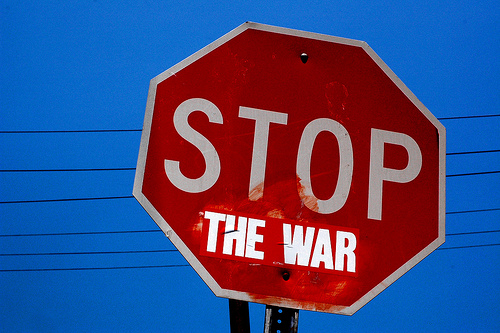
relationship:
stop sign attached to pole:
[130, 17, 446, 314] [257, 305, 301, 332]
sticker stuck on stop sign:
[195, 203, 359, 278] [130, 17, 446, 314]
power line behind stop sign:
[0, 111, 499, 134] [130, 17, 446, 314]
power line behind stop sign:
[1, 149, 499, 176] [130, 17, 446, 314]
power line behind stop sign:
[0, 169, 499, 207] [130, 17, 446, 314]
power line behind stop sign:
[1, 206, 497, 236] [130, 17, 446, 314]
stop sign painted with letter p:
[130, 17, 446, 314] [365, 122, 423, 220]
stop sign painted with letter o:
[130, 17, 446, 314] [293, 117, 354, 214]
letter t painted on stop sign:
[236, 102, 290, 204] [130, 17, 446, 314]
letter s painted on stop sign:
[161, 95, 225, 192] [130, 17, 446, 314]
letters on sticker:
[204, 210, 355, 272] [195, 203, 359, 278]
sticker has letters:
[195, 203, 359, 278] [204, 210, 355, 272]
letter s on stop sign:
[161, 95, 225, 192] [130, 17, 446, 314]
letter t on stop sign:
[236, 102, 290, 204] [130, 17, 446, 314]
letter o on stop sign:
[293, 117, 354, 214] [130, 17, 446, 314]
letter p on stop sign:
[365, 122, 423, 220] [130, 17, 446, 314]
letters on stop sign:
[204, 210, 355, 272] [130, 17, 446, 314]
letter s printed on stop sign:
[161, 95, 225, 192] [130, 17, 446, 314]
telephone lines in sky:
[0, 108, 499, 278] [1, 0, 499, 333]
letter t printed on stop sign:
[236, 102, 290, 204] [130, 17, 446, 314]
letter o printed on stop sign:
[293, 117, 354, 214] [130, 17, 446, 314]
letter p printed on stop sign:
[365, 122, 423, 220] [130, 17, 446, 314]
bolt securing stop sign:
[277, 268, 293, 281] [130, 17, 446, 314]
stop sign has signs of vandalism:
[130, 17, 446, 314] [189, 171, 359, 313]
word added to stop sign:
[202, 210, 267, 260] [130, 17, 446, 314]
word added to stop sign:
[280, 220, 358, 276] [130, 17, 446, 314]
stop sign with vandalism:
[130, 17, 446, 314] [189, 171, 359, 313]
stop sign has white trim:
[130, 17, 446, 314] [130, 20, 447, 318]